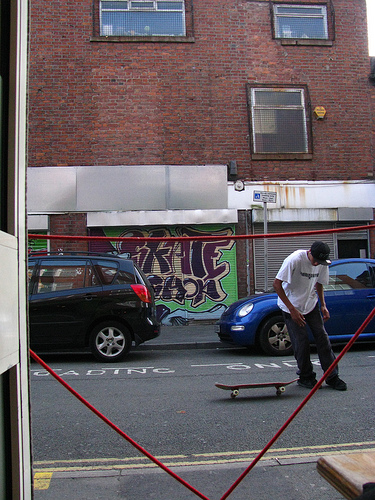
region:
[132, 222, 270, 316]
graffiti on building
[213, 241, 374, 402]
man skateboarding in street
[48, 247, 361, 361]
cars parked along street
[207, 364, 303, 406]
skateboard on two wheels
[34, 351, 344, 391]
white lettering painted on street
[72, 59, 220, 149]
red brick building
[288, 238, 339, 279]
man wearing a black hat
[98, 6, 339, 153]
three windows on building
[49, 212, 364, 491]
red rope along street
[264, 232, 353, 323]
man wearing a white t-shirt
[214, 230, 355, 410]
boy with skateboard in street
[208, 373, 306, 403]
skateboard on the ground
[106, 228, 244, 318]
graffiti on a steel gate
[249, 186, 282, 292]
street sign on metal pole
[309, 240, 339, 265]
baseball cap of a boy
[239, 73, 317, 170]
window of a building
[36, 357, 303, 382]
white painted letters on the street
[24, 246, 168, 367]
black vehicle parked on side of street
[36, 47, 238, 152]
red brick wall of a building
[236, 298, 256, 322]
headlight of a blue car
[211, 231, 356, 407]
man in street looking down at skateboard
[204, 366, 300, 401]
skateboard is in the street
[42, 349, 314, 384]
white lettering on the street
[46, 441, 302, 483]
yellow lines on the street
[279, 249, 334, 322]
man wearing white t shirt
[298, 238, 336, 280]
man wearing black baseball cap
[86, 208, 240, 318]
graffiti on building about skateboarding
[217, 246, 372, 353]
blue compact car is behind the man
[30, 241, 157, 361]
black suv is parked in front of blue compact car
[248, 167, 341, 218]
rust marks on building trim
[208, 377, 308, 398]
a red and black skateboard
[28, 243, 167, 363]
a small black car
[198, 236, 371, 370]
a small blue car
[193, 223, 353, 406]
a boy riding a skateboard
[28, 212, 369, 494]
a red rope barrier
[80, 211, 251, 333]
graffiti on a wall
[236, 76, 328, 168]
a small apartment window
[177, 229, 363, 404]
a boy doing skateboard tricks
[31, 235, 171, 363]
a parked black car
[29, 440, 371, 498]
a concrete city sidewalk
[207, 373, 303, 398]
A skateboard on the street.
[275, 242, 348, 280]
A young boy in a dark hat.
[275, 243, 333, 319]
A white short sleeve shirt.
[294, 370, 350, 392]
A pair of dark tennis shoes.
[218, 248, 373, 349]
A blue car.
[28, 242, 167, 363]
The back half of a dark vehicle.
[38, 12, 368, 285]
A red brick building.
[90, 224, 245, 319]
Graffiti on a building.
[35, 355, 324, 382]
White writing painted on street.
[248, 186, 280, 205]
A small square sign.